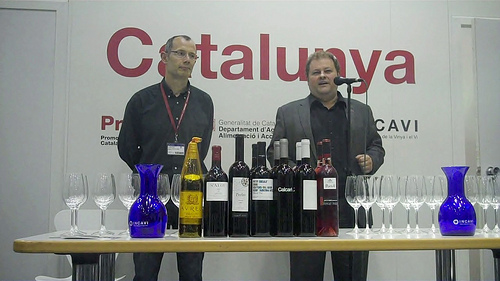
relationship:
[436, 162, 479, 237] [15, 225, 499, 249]
vase at right of table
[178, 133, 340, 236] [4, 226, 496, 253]
wine bottles on table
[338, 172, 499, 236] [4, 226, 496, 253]
glasses on table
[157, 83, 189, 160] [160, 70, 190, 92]
lanyard around man's neck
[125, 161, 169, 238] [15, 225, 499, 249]
vase left on blue table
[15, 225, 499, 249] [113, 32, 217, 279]
table in front of man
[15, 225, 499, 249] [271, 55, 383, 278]
table in front of man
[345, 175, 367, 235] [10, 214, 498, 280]
wine glass on table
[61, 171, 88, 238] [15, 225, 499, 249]
glass on table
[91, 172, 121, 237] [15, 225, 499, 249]
glass on table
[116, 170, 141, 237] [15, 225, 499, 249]
glass on table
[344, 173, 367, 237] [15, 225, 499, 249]
glass on table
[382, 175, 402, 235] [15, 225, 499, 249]
glass on table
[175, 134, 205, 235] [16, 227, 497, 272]
wine bottle on table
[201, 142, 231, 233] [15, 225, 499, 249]
wine on table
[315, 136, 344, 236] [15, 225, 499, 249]
bottle on table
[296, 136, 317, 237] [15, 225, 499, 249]
bottle on table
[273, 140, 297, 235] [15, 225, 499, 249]
bottle on table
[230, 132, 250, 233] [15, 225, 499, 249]
bottle on table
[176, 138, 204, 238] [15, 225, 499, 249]
bottle on table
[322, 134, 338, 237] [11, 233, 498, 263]
bottle on table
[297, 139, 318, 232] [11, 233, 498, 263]
bottle on table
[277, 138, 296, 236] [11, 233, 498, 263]
bottle on table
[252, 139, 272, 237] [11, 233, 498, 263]
bottle on table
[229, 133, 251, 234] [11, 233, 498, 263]
bottle on table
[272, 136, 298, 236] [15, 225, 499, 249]
wine on table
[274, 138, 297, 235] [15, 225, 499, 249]
wine bottle on table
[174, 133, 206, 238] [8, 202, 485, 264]
wine on table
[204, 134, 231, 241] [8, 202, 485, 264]
wine on table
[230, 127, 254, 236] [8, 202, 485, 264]
wine on table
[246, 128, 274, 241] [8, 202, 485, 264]
wine on table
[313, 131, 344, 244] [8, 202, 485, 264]
wine on table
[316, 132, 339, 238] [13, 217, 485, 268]
wine bottle on table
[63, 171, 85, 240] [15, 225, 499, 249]
wine glass on table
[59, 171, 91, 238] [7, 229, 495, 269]
glass on table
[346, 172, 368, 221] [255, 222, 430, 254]
glass on table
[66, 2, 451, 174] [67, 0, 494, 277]
catalunya sign on wall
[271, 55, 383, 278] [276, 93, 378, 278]
man wears suit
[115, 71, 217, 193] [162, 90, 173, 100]
shirt has buttons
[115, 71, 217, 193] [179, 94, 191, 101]
shirt has buttons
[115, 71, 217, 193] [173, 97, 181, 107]
shirt has buttons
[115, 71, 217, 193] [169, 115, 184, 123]
shirt has buttons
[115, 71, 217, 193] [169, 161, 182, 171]
shirt has buttons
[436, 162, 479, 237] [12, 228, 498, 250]
vase on table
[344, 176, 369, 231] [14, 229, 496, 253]
wine glass on table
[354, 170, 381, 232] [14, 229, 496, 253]
wine glass on table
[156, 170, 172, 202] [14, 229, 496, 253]
wine glass on table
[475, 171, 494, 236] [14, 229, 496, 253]
wine glass on table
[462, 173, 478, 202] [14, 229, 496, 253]
wine glass on table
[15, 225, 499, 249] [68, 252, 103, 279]
table has leg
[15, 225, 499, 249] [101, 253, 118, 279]
table has leg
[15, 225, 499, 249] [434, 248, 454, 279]
table has leg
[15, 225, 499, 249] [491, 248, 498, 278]
table has leg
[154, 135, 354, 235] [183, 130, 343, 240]
wine bottles on table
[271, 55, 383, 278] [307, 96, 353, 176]
man wearing shirt